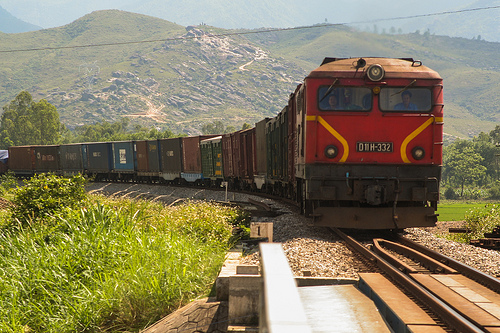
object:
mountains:
[0, 8, 500, 94]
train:
[17, 50, 446, 230]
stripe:
[317, 116, 352, 162]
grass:
[0, 183, 231, 330]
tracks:
[344, 220, 500, 333]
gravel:
[283, 211, 500, 277]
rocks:
[180, 72, 200, 82]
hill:
[0, 5, 491, 133]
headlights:
[325, 145, 339, 158]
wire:
[0, 6, 498, 54]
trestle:
[365, 239, 499, 331]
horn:
[352, 57, 367, 78]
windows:
[317, 87, 376, 112]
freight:
[0, 119, 269, 187]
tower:
[323, 17, 329, 24]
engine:
[306, 61, 445, 221]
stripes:
[399, 117, 434, 163]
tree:
[372, 23, 379, 34]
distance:
[0, 1, 497, 57]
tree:
[381, 26, 389, 35]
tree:
[398, 26, 403, 34]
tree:
[414, 29, 421, 35]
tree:
[423, 26, 431, 37]